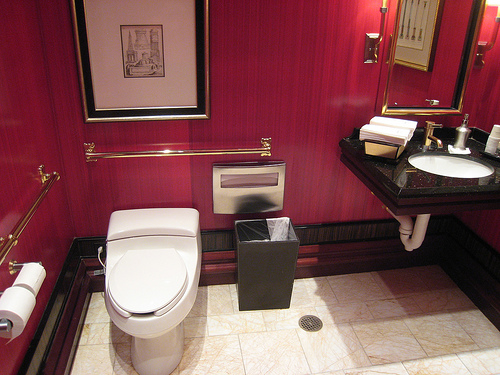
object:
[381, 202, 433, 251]
drainage pipe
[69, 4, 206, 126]
picture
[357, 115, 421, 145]
paper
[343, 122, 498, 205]
counter top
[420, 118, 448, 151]
faucet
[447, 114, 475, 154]
dispenser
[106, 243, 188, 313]
lid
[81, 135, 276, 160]
rails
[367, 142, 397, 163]
basket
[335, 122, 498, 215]
marble sink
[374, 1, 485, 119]
mirror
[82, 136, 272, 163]
racks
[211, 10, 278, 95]
wall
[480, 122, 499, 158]
cups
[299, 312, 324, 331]
drainer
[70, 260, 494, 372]
floor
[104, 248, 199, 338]
seat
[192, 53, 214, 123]
framed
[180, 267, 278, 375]
toilet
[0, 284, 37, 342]
rolls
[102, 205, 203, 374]
commode